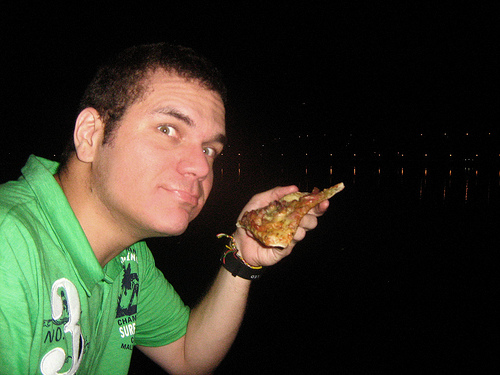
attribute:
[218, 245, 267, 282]
watch — black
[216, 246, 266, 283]
watch —  for wrist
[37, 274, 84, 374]
3 — large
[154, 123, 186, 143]
eye — green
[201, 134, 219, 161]
eye — green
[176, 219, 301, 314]
bracelet — multi colored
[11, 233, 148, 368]
shirt — green 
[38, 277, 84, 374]
number three — white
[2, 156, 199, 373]
shirt — polo, green, green polo 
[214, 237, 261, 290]
rubber bracelet — Black 